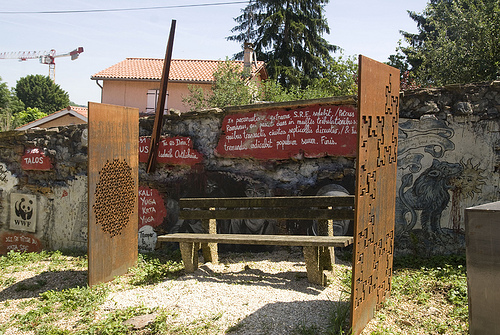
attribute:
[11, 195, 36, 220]
panda — black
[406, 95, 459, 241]
wall — stone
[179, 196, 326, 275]
bench — stone, brown, wooden, empty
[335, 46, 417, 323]
planks — iron, metal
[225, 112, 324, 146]
writing — white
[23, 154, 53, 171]
sign — red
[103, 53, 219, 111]
building — pink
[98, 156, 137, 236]
designs — round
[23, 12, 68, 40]
sky — blue, sunny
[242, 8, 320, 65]
tree — green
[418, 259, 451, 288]
grass — green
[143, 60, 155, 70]
tile — clay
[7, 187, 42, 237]
poster — wwf